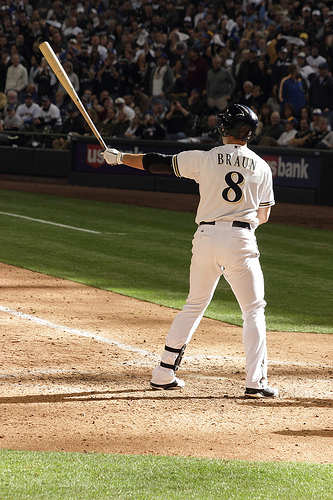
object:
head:
[214, 97, 260, 142]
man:
[100, 102, 275, 404]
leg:
[221, 237, 274, 403]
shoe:
[243, 377, 277, 398]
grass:
[0, 184, 332, 334]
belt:
[198, 215, 259, 230]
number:
[219, 169, 245, 203]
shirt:
[174, 129, 275, 225]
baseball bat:
[34, 36, 107, 152]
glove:
[100, 142, 127, 165]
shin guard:
[154, 332, 183, 372]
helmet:
[221, 105, 258, 141]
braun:
[215, 147, 258, 173]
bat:
[38, 38, 71, 82]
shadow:
[0, 385, 186, 407]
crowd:
[122, 16, 274, 109]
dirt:
[59, 286, 110, 327]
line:
[0, 298, 161, 384]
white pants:
[161, 222, 268, 376]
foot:
[244, 381, 280, 401]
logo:
[268, 153, 311, 180]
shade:
[184, 8, 230, 51]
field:
[0, 178, 332, 497]